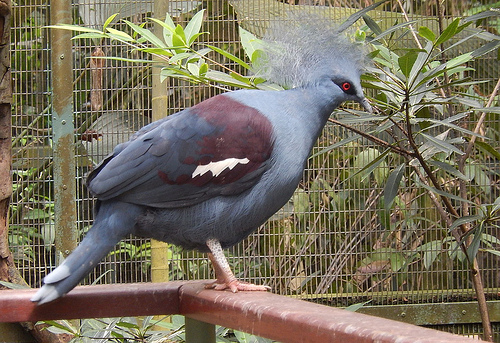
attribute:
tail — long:
[56, 144, 147, 296]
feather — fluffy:
[62, 17, 402, 310]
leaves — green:
[48, 7, 234, 92]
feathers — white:
[29, 7, 371, 310]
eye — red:
[342, 80, 348, 88]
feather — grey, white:
[93, 153, 150, 185]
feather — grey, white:
[41, 220, 103, 287]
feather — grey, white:
[36, 220, 132, 309]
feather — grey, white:
[25, 274, 62, 306]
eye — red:
[339, 80, 353, 96]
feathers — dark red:
[159, 90, 282, 198]